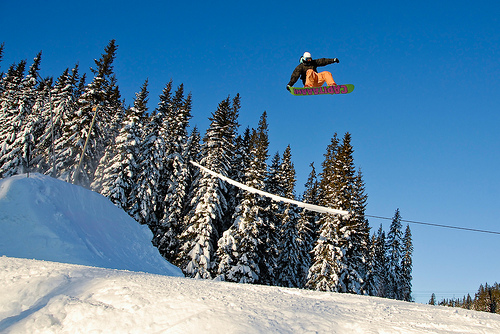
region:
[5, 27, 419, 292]
Group of evergreen trees with snow on top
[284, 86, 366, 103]
Pink and green snowboard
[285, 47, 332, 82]
Black jacket on snowboarder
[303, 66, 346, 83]
Orange pants on snowboarder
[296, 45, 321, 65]
White helmet on snowboarder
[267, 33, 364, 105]
Snowboarder doing a jump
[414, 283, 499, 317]
Group of regular green trees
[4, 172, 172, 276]
Snowboard ramp made of snow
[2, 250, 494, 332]
Ground covered with snow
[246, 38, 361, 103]
Snowboarder in the air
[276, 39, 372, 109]
snow board flying high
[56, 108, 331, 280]
pine tree covered with snow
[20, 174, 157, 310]
snow in the mountain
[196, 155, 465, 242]
electric line with the snow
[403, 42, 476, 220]
a clear blue sky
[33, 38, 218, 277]
pine tree with snows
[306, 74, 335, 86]
a man wearing orange color pant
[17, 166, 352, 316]
place covered fluu of snow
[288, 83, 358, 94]
green color snow board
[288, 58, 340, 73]
man wearing black color jacket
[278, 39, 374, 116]
snowboarder doing a jump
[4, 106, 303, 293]
Group of trees with snow on top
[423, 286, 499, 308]
Small group of bare trees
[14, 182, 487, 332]
Deep white snow on the ground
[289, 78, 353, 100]
Green and red snowboard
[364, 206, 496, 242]
Black wire in the sky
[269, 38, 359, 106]
Snowboarder doing a cool trick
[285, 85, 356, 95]
green and pink snowboard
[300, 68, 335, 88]
orange pants on a snowboarder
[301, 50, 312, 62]
white helmet on a snowboarder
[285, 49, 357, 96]
snowboarder in the air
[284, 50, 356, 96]
person on a snowboard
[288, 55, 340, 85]
black coat on a snowboarder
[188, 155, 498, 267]
black powerline partially covered with ice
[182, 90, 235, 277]
tall pine tree covered in snow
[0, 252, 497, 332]
lots of snow covering the ground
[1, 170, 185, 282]
small hill of snow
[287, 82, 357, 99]
green snowboard flying through air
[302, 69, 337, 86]
orange snow pants on person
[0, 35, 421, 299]
grove of trees with snow on them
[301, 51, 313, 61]
white hat on person's head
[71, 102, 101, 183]
pole sticking out of snow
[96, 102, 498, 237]
wire hanging from pole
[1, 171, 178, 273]
snowbank piled up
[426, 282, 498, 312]
hill full of trees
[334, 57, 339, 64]
black glove on person's hand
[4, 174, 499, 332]
white snow all over ground